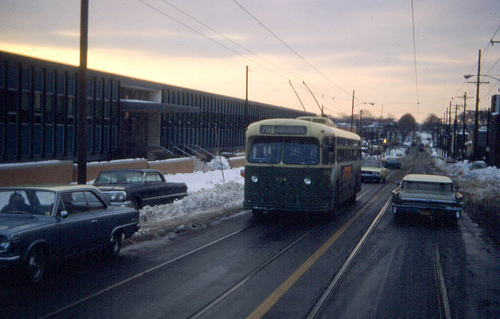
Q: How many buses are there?
A: One.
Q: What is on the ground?
A: Snow.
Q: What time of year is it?
A: Winter.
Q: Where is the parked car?
A: By the curb.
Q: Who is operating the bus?
A: The bus driver.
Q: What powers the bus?
A: Fuel.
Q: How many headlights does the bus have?
A: Two.